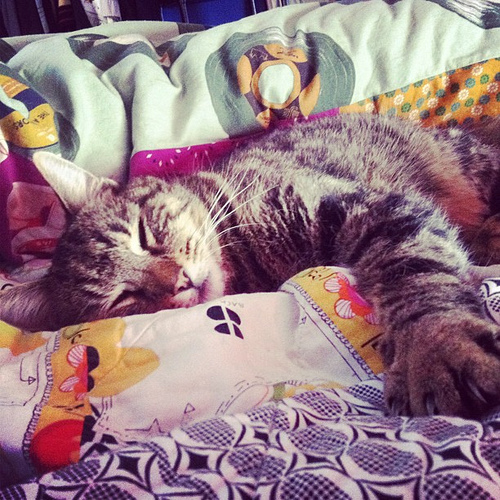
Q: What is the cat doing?
A: Sleeping.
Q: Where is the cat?
A: On the blanket.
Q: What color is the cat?
A: Grey.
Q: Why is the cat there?
A: It lives there.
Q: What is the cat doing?
A: Laying down.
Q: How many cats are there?
A: One.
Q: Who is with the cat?
A: Nobody.